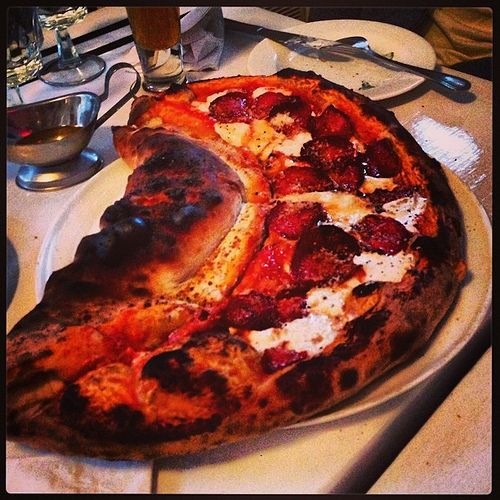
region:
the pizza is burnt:
[1, 65, 472, 461]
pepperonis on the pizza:
[210, 91, 415, 342]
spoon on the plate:
[333, 31, 473, 119]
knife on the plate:
[223, 14, 374, 65]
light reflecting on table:
[401, 111, 491, 196]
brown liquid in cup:
[123, 3, 184, 53]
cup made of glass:
[121, 6, 186, 98]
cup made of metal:
[6, 59, 143, 194]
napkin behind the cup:
[176, 7, 229, 74]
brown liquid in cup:
[7, 119, 80, 154]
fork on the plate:
[321, 32, 478, 106]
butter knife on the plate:
[229, 16, 330, 54]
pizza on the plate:
[6, 75, 465, 454]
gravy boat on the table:
[3, 54, 142, 194]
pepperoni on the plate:
[208, 93, 260, 125]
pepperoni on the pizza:
[287, 227, 355, 281]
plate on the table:
[243, 18, 433, 111]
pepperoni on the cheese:
[352, 204, 409, 254]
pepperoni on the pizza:
[313, 107, 358, 144]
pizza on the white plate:
[7, 68, 492, 461]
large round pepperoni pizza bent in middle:
[9, 67, 465, 457]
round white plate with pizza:
[29, 115, 497, 477]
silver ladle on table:
[10, 58, 140, 191]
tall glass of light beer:
[119, 1, 194, 92]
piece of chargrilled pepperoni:
[285, 222, 361, 292]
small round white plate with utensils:
[240, 15, 439, 114]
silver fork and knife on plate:
[290, 20, 475, 105]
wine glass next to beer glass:
[37, 3, 108, 87]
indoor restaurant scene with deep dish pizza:
[14, 0, 498, 492]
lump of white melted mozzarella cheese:
[250, 285, 355, 359]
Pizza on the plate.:
[7, 76, 466, 461]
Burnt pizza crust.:
[37, 176, 224, 311]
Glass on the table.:
[114, 3, 194, 96]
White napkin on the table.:
[2, 435, 164, 498]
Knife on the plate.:
[227, 13, 369, 62]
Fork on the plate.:
[329, 30, 473, 95]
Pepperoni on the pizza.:
[354, 210, 409, 258]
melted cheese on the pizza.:
[257, 313, 334, 352]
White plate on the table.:
[246, 14, 441, 106]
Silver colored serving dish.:
[4, 60, 144, 194]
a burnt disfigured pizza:
[8, 55, 484, 447]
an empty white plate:
[246, 7, 446, 102]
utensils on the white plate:
[216, 16, 479, 100]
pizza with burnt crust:
[10, 72, 457, 453]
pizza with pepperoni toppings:
[13, 72, 458, 458]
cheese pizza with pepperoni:
[26, 62, 449, 474]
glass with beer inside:
[126, 0, 193, 88]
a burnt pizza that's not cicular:
[0, 73, 482, 444]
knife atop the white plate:
[218, 9, 371, 71]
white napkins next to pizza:
[8, 437, 167, 494]